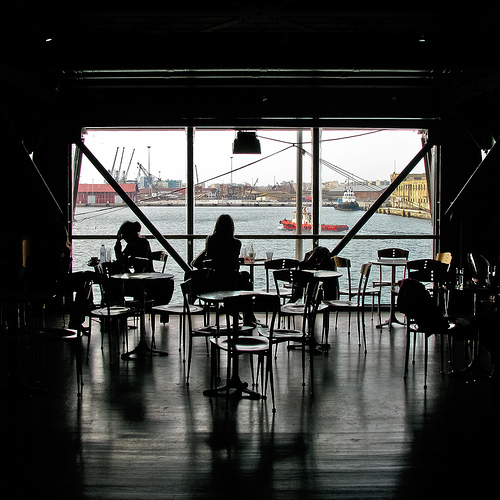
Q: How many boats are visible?
A: Two.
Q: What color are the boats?
A: Red and black.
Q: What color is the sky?
A: Blue.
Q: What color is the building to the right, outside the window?
A: Yellow.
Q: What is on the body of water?
A: Boats.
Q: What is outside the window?
A: A body of water.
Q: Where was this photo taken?
A: Inside a restaurant.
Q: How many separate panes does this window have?
A: Six.